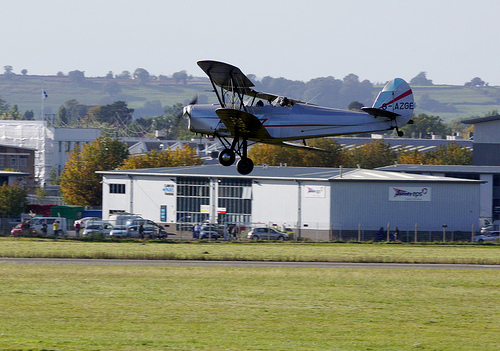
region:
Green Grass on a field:
[23, 280, 185, 348]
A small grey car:
[252, 225, 288, 242]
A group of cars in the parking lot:
[86, 216, 161, 242]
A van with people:
[16, 217, 73, 241]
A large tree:
[69, 143, 101, 200]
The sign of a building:
[378, 182, 440, 209]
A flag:
[36, 84, 56, 121]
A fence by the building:
[365, 220, 491, 247]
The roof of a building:
[458, 109, 494, 144]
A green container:
[51, 201, 86, 216]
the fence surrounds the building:
[10, 206, 498, 247]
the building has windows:
[176, 175, 252, 235]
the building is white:
[95, 172, 488, 245]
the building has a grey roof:
[96, 161, 486, 190]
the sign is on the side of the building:
[384, 182, 435, 202]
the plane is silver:
[178, 49, 417, 179]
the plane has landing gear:
[211, 138, 261, 179]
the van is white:
[20, 211, 69, 240]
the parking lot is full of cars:
[5, 210, 300, 244]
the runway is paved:
[1, 252, 499, 275]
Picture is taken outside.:
[16, 13, 491, 336]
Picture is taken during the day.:
[21, 13, 468, 102]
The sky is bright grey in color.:
[69, 15, 479, 80]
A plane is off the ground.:
[164, 55, 442, 207]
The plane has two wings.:
[164, 48, 454, 173]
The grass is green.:
[64, 260, 243, 349]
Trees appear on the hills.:
[36, 47, 206, 104]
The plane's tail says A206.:
[350, 58, 432, 165]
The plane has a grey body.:
[192, 87, 482, 148]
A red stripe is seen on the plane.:
[169, 94, 421, 140]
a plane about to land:
[103, 56, 456, 180]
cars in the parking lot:
[7, 196, 295, 260]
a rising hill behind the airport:
[23, 46, 463, 114]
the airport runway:
[9, 239, 476, 286]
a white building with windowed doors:
[97, 161, 463, 239]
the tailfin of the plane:
[346, 71, 438, 145]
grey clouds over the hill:
[47, 3, 432, 58]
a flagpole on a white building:
[26, 76, 72, 141]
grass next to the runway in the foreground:
[46, 268, 448, 333]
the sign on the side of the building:
[377, 171, 452, 213]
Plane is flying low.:
[160, 46, 435, 177]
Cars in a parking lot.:
[9, 203, 295, 253]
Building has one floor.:
[81, 144, 499, 244]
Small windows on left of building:
[102, 176, 129, 195]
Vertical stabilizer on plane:
[364, 76, 421, 115]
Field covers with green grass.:
[7, 264, 499, 344]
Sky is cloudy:
[6, 6, 491, 82]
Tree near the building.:
[55, 131, 135, 209]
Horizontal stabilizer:
[360, 104, 405, 124]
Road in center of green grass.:
[1, 246, 498, 276]